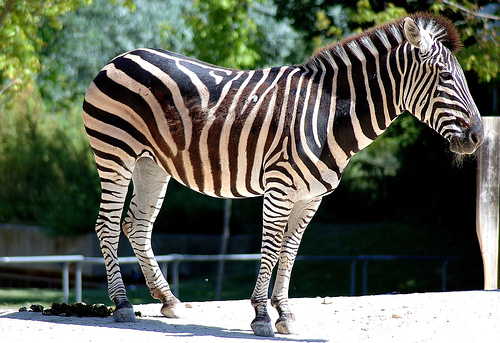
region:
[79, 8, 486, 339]
Zebra with black and white stripes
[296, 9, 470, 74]
black and white striped zebra mane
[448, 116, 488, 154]
all black zebra nose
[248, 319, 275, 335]
Gray colored zebra hoof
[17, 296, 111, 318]
pile of fresh zebra droppings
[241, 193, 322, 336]
two front zebra legs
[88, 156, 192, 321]
two back zebra legs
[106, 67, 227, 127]
black and white zebra stripes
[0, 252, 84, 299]
blueish gray hand railing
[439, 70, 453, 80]
zebra front right eye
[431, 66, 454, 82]
the right eye of the zebra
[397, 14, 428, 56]
the right ear of the zebra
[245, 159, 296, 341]
the front right leg of the zebra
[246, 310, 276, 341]
the front right hoof of the zebra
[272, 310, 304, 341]
the front left hoof of the zebra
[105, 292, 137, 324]
the back right hoof of the zebra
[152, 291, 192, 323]
the back left hoof of the zebra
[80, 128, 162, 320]
the back right leg of the zebra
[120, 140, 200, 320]
the back left leg of the zebra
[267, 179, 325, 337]
the front left leg of the zebra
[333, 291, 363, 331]
part of a floor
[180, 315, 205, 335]
part of a shade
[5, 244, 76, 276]
the pole is white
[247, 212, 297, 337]
the zebra has front legs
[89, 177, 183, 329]
the zebra has rear legs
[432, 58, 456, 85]
the zebra has an eye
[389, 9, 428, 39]
the zebra has an ear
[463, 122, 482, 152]
the zebra has a nose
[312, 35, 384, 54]
the zebra has a mane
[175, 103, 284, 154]
the zebra has stripes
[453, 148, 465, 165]
the zebra has whiskers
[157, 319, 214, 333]
the zebra has a shadow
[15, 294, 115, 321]
pile of zebra poop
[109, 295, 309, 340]
zebra hooves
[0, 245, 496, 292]
metal fence around the zebra pen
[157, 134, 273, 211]
zebra belly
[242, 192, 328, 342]
a zebra's front legs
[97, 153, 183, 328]
a zebra's back legs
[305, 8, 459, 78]
black and white mane on the zebra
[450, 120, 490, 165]
black nostrils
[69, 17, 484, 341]
a zebra standing alone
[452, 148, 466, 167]
hair from the zebra's face